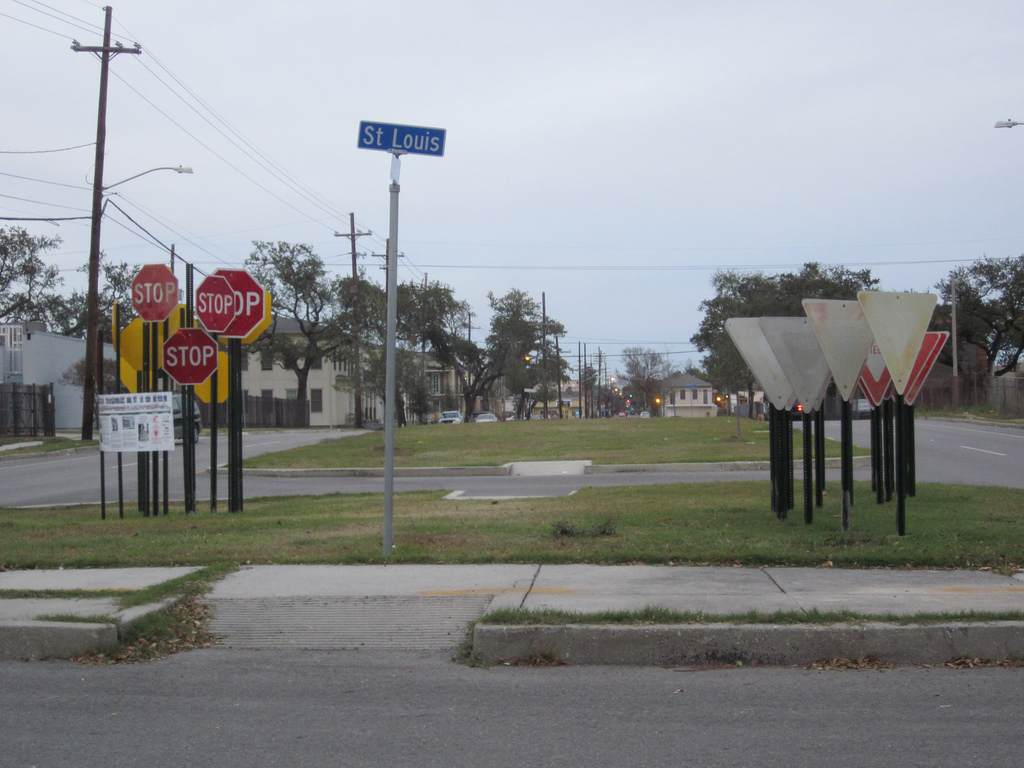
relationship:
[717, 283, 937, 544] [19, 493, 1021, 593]
signs on lawn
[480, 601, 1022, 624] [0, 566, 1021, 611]
grass on sidewalk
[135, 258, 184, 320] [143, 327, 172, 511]
stop sign on pole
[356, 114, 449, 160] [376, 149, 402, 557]
sign on pole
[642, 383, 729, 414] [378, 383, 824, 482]
traffic lights across lawn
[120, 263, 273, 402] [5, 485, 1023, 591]
signs on lawn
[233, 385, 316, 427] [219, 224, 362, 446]
fence near tree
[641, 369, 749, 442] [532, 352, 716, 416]
house surrounding lights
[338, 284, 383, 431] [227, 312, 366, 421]
tree near house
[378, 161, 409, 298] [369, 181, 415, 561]
sign on a pole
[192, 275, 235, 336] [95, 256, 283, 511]
sign on a pole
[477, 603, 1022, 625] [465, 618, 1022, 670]
grass growing on curb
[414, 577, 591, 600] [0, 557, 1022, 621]
line on sidewalk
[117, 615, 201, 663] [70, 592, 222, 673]
leaves in gutter